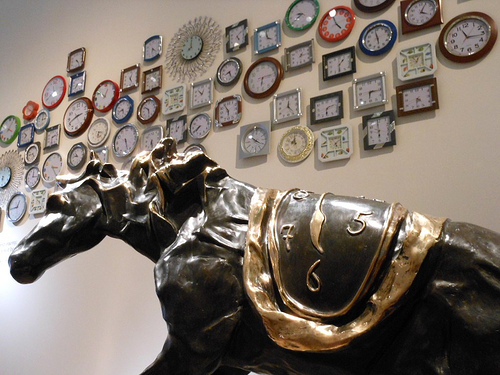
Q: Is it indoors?
A: Yes, it is indoors.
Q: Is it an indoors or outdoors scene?
A: It is indoors.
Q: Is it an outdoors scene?
A: No, it is indoors.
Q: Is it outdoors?
A: No, it is indoors.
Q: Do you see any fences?
A: No, there are no fences.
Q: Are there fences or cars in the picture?
A: No, there are no fences or cars.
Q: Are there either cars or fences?
A: No, there are no fences or cars.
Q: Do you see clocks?
A: Yes, there is a clock.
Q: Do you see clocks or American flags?
A: Yes, there is a clock.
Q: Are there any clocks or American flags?
A: Yes, there is a clock.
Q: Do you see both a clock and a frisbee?
A: No, there is a clock but no frisbees.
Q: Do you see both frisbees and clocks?
A: No, there is a clock but no frisbees.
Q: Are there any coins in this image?
A: No, there are no coins.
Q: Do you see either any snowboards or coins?
A: No, there are no coins or snowboards.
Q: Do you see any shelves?
A: No, there are no shelves.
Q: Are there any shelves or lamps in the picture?
A: No, there are no shelves or lamps.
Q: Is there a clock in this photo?
A: Yes, there is a clock.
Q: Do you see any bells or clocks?
A: Yes, there is a clock.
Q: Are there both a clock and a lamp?
A: No, there is a clock but no lamps.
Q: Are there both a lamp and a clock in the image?
A: No, there is a clock but no lamps.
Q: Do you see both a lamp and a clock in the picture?
A: No, there is a clock but no lamps.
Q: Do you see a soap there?
A: No, there are no soaps.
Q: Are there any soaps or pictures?
A: No, there are no soaps or pictures.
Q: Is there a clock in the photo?
A: Yes, there is a clock.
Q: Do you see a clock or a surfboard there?
A: Yes, there is a clock.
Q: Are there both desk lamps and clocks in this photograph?
A: No, there is a clock but no desk lamps.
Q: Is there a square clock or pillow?
A: Yes, there is a square clock.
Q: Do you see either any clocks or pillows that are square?
A: Yes, the clock is square.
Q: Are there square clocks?
A: Yes, there is a square clock.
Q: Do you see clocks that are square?
A: Yes, there is a square clock.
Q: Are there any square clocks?
A: Yes, there is a square clock.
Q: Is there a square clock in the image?
A: Yes, there is a square clock.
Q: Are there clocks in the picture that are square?
A: Yes, there is a clock that is square.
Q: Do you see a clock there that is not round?
A: Yes, there is a square clock.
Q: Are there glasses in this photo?
A: No, there are no glasses.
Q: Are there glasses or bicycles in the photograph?
A: No, there are no glasses or bicycles.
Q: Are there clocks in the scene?
A: Yes, there is a clock.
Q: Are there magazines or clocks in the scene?
A: Yes, there is a clock.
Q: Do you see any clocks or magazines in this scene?
A: Yes, there is a clock.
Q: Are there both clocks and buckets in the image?
A: No, there is a clock but no buckets.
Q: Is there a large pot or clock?
A: Yes, there is a large clock.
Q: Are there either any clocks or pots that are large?
A: Yes, the clock is large.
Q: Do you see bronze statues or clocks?
A: Yes, there is a bronze clock.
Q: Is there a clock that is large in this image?
A: Yes, there is a large clock.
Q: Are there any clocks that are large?
A: Yes, there is a clock that is large.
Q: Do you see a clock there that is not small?
A: Yes, there is a large clock.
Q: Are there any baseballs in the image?
A: No, there are no baseballs.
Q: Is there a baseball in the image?
A: No, there are no baseballs.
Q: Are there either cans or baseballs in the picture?
A: No, there are no baseballs or cans.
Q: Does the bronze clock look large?
A: Yes, the clock is large.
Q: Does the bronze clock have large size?
A: Yes, the clock is large.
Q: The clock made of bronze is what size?
A: The clock is large.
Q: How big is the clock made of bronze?
A: The clock is large.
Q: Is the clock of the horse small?
A: No, the clock is large.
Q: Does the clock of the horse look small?
A: No, the clock is large.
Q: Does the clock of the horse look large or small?
A: The clock is large.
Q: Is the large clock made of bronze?
A: Yes, the clock is made of bronze.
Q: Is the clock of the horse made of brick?
A: No, the clock is made of bronze.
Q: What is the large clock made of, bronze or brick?
A: The clock is made of bronze.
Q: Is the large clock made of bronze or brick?
A: The clock is made of bronze.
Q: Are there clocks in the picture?
A: Yes, there is a clock.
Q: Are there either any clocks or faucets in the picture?
A: Yes, there is a clock.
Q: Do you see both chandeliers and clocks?
A: No, there is a clock but no chandeliers.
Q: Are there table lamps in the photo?
A: No, there are no table lamps.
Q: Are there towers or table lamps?
A: No, there are no table lamps or towers.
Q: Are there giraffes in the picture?
A: No, there are no giraffes.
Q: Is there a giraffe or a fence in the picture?
A: No, there are no giraffes or fences.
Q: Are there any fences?
A: No, there are no fences.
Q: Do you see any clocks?
A: Yes, there is a clock.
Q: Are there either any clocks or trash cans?
A: Yes, there is a clock.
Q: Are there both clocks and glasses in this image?
A: No, there is a clock but no glasses.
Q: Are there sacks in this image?
A: No, there are no sacks.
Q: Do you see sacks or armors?
A: No, there are no sacks or armors.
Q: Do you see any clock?
A: Yes, there is a clock.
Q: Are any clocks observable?
A: Yes, there is a clock.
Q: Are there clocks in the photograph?
A: Yes, there is a clock.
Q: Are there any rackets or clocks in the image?
A: Yes, there is a clock.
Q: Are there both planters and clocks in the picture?
A: No, there is a clock but no planters.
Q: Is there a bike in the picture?
A: No, there are no bikes.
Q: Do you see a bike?
A: No, there are no bikes.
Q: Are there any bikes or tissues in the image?
A: No, there are no bikes or tissues.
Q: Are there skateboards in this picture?
A: No, there are no skateboards.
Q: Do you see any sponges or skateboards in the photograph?
A: No, there are no skateboards or sponges.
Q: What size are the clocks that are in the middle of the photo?
A: The clocks are small.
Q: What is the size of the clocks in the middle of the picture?
A: The clocks are small.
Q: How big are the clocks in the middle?
A: The clocks are small.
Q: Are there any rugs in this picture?
A: No, there are no rugs.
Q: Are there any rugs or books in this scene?
A: No, there are no rugs or books.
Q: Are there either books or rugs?
A: No, there are no rugs or books.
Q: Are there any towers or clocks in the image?
A: Yes, there is a clock.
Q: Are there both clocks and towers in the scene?
A: No, there is a clock but no towers.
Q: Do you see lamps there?
A: No, there are no lamps.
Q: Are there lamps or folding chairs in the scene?
A: No, there are no lamps or folding chairs.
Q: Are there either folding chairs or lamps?
A: No, there are no lamps or folding chairs.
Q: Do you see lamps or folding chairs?
A: No, there are no lamps or folding chairs.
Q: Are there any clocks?
A: Yes, there is a clock.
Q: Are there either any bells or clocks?
A: Yes, there is a clock.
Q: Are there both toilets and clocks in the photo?
A: No, there is a clock but no toilets.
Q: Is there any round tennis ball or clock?
A: Yes, there is a round clock.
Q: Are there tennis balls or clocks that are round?
A: Yes, the clock is round.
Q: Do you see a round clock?
A: Yes, there is a round clock.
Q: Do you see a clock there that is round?
A: Yes, there is a clock that is round.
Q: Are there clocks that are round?
A: Yes, there is a clock that is round.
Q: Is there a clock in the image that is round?
A: Yes, there is a clock that is round.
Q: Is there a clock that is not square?
A: Yes, there is a round clock.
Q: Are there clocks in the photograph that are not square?
A: Yes, there is a round clock.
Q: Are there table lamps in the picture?
A: No, there are no table lamps.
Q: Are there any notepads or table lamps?
A: No, there are no table lamps or notepads.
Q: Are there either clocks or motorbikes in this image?
A: Yes, there is a clock.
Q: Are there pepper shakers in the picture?
A: No, there are no pepper shakers.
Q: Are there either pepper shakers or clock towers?
A: No, there are no pepper shakers or clock towers.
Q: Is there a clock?
A: Yes, there is a clock.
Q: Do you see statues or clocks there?
A: Yes, there is a clock.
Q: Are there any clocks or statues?
A: Yes, there is a clock.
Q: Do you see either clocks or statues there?
A: Yes, there is a clock.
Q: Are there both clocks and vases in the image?
A: No, there is a clock but no vases.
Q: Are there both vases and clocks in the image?
A: No, there is a clock but no vases.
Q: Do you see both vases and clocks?
A: No, there is a clock but no vases.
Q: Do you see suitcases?
A: No, there are no suitcases.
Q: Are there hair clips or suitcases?
A: No, there are no suitcases or hair clips.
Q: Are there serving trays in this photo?
A: No, there are no serving trays.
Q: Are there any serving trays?
A: No, there are no serving trays.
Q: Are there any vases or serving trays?
A: No, there are no serving trays or vases.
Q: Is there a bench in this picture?
A: No, there are no benches.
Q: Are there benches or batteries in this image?
A: No, there are no benches or batteries.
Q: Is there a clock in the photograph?
A: Yes, there is a clock.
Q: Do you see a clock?
A: Yes, there is a clock.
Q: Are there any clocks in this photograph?
A: Yes, there is a clock.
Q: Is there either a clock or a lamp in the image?
A: Yes, there is a clock.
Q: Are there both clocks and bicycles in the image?
A: No, there is a clock but no bicycles.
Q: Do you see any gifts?
A: No, there are no gifts.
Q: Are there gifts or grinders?
A: No, there are no gifts or grinders.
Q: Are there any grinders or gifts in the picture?
A: No, there are no gifts or grinders.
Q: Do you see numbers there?
A: Yes, there are numbers.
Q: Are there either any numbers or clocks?
A: Yes, there are numbers.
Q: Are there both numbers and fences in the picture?
A: No, there are numbers but no fences.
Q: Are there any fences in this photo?
A: No, there are no fences.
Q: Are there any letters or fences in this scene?
A: No, there are no fences or letters.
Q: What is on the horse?
A: The numbers are on the horse.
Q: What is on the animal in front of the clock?
A: The numbers are on the horse.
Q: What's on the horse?
A: The numbers are on the horse.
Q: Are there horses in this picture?
A: Yes, there is a horse.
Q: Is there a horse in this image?
A: Yes, there is a horse.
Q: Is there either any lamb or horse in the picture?
A: Yes, there is a horse.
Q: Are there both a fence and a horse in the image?
A: No, there is a horse but no fences.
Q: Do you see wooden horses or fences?
A: Yes, there is a wood horse.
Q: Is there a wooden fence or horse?
A: Yes, there is a wood horse.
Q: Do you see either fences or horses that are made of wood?
A: Yes, the horse is made of wood.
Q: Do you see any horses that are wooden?
A: Yes, there is a wood horse.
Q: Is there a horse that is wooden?
A: Yes, there is a horse that is wooden.